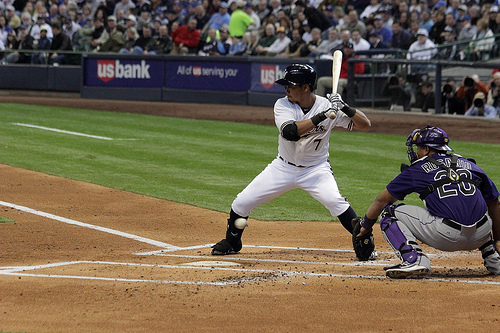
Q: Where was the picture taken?
A: It was taken at the field.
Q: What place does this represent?
A: It represents the field.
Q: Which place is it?
A: It is a field.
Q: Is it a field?
A: Yes, it is a field.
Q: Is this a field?
A: Yes, it is a field.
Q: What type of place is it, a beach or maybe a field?
A: It is a field.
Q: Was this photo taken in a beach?
A: No, the picture was taken in a field.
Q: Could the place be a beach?
A: No, it is a field.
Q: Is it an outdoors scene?
A: Yes, it is outdoors.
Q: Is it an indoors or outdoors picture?
A: It is outdoors.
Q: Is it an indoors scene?
A: No, it is outdoors.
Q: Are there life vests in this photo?
A: No, there are no life vests.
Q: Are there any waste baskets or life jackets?
A: No, there are no life jackets or waste baskets.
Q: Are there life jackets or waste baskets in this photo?
A: No, there are no life jackets or waste baskets.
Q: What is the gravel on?
A: The gravel is on the home plate.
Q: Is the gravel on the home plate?
A: Yes, the gravel is on the home plate.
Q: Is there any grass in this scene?
A: Yes, there is grass.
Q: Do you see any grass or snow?
A: Yes, there is grass.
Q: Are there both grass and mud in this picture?
A: No, there is grass but no mud.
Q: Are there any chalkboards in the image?
A: No, there are no chalkboards.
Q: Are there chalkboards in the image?
A: No, there are no chalkboards.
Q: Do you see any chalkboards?
A: No, there are no chalkboards.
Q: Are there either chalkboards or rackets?
A: No, there are no chalkboards or rackets.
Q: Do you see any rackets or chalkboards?
A: No, there are no chalkboards or rackets.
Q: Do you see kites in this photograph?
A: No, there are no kites.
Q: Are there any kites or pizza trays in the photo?
A: No, there are no kites or pizza trays.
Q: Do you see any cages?
A: No, there are no cages.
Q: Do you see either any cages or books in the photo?
A: No, there are no cages or books.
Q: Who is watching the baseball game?
A: The crowd is watching the game.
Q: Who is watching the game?
A: The crowd is watching the game.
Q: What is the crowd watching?
A: The crowd is watching the game.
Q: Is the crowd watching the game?
A: Yes, the crowd is watching the game.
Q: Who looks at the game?
A: The crowd looks at the game.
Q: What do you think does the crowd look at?
A: The crowd looks at the game.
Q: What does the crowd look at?
A: The crowd looks at the game.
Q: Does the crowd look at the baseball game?
A: Yes, the crowd looks at the game.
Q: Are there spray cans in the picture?
A: No, there are no spray cans.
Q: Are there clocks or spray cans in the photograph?
A: No, there are no spray cans or clocks.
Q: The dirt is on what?
A: The dirt is on the home plate.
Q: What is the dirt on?
A: The dirt is on the home plate.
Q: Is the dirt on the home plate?
A: Yes, the dirt is on the home plate.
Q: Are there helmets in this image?
A: Yes, there is a helmet.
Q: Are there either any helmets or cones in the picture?
A: Yes, there is a helmet.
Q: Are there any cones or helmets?
A: Yes, there is a helmet.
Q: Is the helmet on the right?
A: Yes, the helmet is on the right of the image.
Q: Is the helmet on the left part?
A: No, the helmet is on the right of the image.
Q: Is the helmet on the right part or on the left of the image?
A: The helmet is on the right of the image.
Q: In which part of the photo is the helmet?
A: The helmet is on the right of the image.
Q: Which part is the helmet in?
A: The helmet is on the right of the image.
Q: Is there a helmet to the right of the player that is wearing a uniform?
A: Yes, there is a helmet to the right of the player.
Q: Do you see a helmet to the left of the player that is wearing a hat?
A: No, the helmet is to the right of the player.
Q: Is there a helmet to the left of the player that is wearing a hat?
A: No, the helmet is to the right of the player.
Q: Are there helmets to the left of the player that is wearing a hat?
A: No, the helmet is to the right of the player.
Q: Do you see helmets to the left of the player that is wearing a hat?
A: No, the helmet is to the right of the player.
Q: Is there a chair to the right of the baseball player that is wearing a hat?
A: No, there is a helmet to the right of the player.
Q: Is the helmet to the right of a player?
A: Yes, the helmet is to the right of a player.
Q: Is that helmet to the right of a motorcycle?
A: No, the helmet is to the right of a player.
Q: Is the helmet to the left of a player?
A: No, the helmet is to the right of a player.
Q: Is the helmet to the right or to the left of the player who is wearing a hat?
A: The helmet is to the right of the player.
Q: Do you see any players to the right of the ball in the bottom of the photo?
A: Yes, there is a player to the right of the ball.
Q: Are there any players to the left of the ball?
A: No, the player is to the right of the ball.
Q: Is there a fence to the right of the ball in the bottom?
A: No, there is a player to the right of the ball.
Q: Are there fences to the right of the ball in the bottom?
A: No, there is a player to the right of the ball.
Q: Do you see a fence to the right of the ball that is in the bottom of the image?
A: No, there is a player to the right of the ball.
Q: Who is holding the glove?
A: The player is holding the glove.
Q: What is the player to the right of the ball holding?
A: The player is holding the glove.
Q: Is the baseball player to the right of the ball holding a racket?
A: No, the player is holding the glove.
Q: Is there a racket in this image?
A: No, there are no rackets.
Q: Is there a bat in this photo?
A: Yes, there is a bat.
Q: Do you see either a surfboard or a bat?
A: Yes, there is a bat.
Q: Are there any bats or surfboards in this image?
A: Yes, there is a bat.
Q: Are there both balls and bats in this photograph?
A: Yes, there are both a bat and a ball.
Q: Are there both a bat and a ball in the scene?
A: Yes, there are both a bat and a ball.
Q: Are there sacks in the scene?
A: No, there are no sacks.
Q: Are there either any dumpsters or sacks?
A: No, there are no sacks or dumpsters.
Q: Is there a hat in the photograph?
A: Yes, there is a hat.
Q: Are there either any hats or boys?
A: Yes, there is a hat.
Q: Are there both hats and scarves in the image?
A: No, there is a hat but no scarves.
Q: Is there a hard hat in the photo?
A: Yes, there is a hard hat.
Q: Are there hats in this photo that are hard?
A: Yes, there is a hat that is hard.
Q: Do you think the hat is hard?
A: Yes, the hat is hard.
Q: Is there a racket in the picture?
A: No, there are no rackets.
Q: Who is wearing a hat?
A: The player is wearing a hat.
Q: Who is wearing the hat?
A: The player is wearing a hat.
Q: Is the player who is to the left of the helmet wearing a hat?
A: Yes, the player is wearing a hat.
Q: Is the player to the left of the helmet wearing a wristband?
A: No, the player is wearing a hat.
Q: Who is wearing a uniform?
A: The player is wearing a uniform.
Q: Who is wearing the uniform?
A: The player is wearing a uniform.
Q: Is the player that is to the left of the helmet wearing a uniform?
A: Yes, the player is wearing a uniform.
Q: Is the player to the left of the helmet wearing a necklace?
A: No, the player is wearing a uniform.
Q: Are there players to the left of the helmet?
A: Yes, there is a player to the left of the helmet.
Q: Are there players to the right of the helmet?
A: No, the player is to the left of the helmet.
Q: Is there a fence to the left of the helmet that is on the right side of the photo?
A: No, there is a player to the left of the helmet.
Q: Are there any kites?
A: No, there are no kites.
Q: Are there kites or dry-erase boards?
A: No, there are no kites or dry-erase boards.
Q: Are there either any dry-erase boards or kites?
A: No, there are no kites or dry-erase boards.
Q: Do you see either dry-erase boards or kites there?
A: No, there are no kites or dry-erase boards.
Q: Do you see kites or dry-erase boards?
A: No, there are no kites or dry-erase boards.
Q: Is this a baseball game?
A: Yes, this is a baseball game.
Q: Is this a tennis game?
A: No, this is a baseball game.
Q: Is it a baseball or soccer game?
A: This is a baseball game.